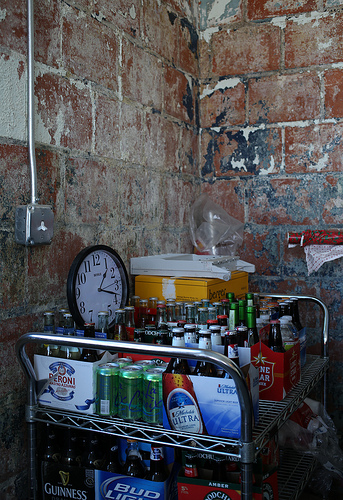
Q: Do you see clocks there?
A: Yes, there is a clock.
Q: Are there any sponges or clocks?
A: Yes, there is a clock.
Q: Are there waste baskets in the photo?
A: No, there are no waste baskets.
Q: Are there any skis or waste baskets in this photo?
A: No, there are no waste baskets or skis.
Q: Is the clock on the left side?
A: Yes, the clock is on the left of the image.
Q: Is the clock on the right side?
A: No, the clock is on the left of the image.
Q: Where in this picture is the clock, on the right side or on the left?
A: The clock is on the left of the image.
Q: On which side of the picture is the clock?
A: The clock is on the left of the image.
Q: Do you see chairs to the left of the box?
A: No, there is a clock to the left of the box.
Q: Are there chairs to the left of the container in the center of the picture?
A: No, there is a clock to the left of the box.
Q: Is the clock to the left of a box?
A: Yes, the clock is to the left of a box.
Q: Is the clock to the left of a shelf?
A: No, the clock is to the left of a box.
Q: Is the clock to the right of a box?
A: No, the clock is to the left of a box.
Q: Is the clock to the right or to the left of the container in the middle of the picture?
A: The clock is to the left of the box.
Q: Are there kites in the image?
A: No, there are no kites.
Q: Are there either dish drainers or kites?
A: No, there are no kites or dish drainers.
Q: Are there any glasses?
A: No, there are no glasses.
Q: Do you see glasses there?
A: No, there are no glasses.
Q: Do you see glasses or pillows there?
A: No, there are no glasses or pillows.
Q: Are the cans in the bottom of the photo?
A: Yes, the cans are in the bottom of the image.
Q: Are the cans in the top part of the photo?
A: No, the cans are in the bottom of the image.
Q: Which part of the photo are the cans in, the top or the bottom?
A: The cans are in the bottom of the image.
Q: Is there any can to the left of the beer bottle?
A: Yes, there are cans to the left of the beer bottle.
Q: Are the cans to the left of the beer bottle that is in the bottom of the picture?
A: Yes, the cans are to the left of the beer bottle.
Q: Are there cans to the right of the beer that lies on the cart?
A: Yes, there are cans to the right of the beer.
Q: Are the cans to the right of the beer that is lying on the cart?
A: Yes, the cans are to the right of the beer.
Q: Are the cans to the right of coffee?
A: No, the cans are to the right of the beer.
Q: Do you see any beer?
A: Yes, there is beer.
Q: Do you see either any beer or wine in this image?
A: Yes, there is beer.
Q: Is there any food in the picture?
A: No, there is no food.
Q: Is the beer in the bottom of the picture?
A: Yes, the beer is in the bottom of the image.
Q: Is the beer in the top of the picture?
A: No, the beer is in the bottom of the image.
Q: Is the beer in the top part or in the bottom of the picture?
A: The beer is in the bottom of the image.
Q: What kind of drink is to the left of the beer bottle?
A: The drink is beer.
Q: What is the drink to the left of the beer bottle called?
A: The drink is beer.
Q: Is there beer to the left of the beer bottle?
A: Yes, there is beer to the left of the beer bottle.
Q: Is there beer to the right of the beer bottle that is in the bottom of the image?
A: No, the beer is to the left of the beer bottle.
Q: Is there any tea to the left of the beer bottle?
A: No, there is beer to the left of the beer bottle.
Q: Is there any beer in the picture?
A: Yes, there is beer.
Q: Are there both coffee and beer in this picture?
A: No, there is beer but no coffee.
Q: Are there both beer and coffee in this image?
A: No, there is beer but no coffee.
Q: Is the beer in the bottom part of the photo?
A: Yes, the beer is in the bottom of the image.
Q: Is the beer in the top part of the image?
A: No, the beer is in the bottom of the image.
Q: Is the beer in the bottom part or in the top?
A: The beer is in the bottom of the image.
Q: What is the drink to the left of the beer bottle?
A: The drink is beer.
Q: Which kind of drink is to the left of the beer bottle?
A: The drink is beer.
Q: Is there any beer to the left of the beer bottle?
A: Yes, there is beer to the left of the beer bottle.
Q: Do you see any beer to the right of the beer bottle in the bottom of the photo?
A: No, the beer is to the left of the beer bottle.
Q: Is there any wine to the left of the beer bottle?
A: No, there is beer to the left of the beer bottle.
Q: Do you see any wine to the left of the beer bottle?
A: No, there is beer to the left of the beer bottle.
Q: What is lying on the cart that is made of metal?
A: The beer is lying on the cart.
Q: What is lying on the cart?
A: The beer is lying on the cart.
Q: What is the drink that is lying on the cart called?
A: The drink is beer.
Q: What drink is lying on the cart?
A: The drink is beer.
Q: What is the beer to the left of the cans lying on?
A: The beer is lying on the cart.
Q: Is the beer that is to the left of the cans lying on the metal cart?
A: Yes, the beer is lying on the cart.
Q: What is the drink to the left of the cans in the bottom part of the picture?
A: The drink is beer.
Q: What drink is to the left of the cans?
A: The drink is beer.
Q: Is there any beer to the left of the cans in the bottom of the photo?
A: Yes, there is beer to the left of the cans.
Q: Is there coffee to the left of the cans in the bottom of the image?
A: No, there is beer to the left of the cans.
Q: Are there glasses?
A: No, there are no glasses.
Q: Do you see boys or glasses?
A: No, there are no glasses or boys.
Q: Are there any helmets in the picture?
A: No, there are no helmets.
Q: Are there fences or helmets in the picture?
A: No, there are no helmets or fences.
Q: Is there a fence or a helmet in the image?
A: No, there are no helmets or fences.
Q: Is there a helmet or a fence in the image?
A: No, there are no helmets or fences.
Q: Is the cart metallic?
A: Yes, the cart is metallic.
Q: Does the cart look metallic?
A: Yes, the cart is metallic.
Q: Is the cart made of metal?
A: Yes, the cart is made of metal.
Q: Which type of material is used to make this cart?
A: The cart is made of metal.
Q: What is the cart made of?
A: The cart is made of metal.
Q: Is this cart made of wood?
A: No, the cart is made of metal.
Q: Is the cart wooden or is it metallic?
A: The cart is metallic.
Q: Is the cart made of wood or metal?
A: The cart is made of metal.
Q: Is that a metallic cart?
A: Yes, that is a metallic cart.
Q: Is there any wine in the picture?
A: No, there is no wine.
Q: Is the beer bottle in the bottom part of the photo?
A: Yes, the beer bottle is in the bottom of the image.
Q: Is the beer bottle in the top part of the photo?
A: No, the beer bottle is in the bottom of the image.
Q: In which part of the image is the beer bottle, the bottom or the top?
A: The beer bottle is in the bottom of the image.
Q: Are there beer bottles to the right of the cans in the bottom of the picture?
A: Yes, there is a beer bottle to the right of the cans.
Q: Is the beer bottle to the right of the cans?
A: Yes, the beer bottle is to the right of the cans.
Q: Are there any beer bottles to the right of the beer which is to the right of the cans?
A: Yes, there is a beer bottle to the right of the beer.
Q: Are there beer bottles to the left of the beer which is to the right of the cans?
A: No, the beer bottle is to the right of the beer.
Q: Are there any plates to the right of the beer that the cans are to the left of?
A: No, there is a beer bottle to the right of the beer.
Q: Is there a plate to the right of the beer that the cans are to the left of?
A: No, there is a beer bottle to the right of the beer.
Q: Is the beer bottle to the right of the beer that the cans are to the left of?
A: Yes, the beer bottle is to the right of the beer.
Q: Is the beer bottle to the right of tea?
A: No, the beer bottle is to the right of the beer.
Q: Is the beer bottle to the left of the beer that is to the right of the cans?
A: No, the beer bottle is to the right of the beer.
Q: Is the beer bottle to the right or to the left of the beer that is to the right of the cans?
A: The beer bottle is to the right of the beer.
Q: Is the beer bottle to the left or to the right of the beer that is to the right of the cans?
A: The beer bottle is to the right of the beer.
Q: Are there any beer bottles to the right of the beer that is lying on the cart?
A: Yes, there is a beer bottle to the right of the beer.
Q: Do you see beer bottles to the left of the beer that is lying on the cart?
A: No, the beer bottle is to the right of the beer.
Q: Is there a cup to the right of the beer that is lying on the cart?
A: No, there is a beer bottle to the right of the beer.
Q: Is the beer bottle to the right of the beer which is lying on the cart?
A: Yes, the beer bottle is to the right of the beer.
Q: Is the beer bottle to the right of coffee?
A: No, the beer bottle is to the right of the beer.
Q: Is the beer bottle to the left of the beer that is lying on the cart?
A: No, the beer bottle is to the right of the beer.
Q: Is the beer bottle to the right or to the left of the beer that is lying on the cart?
A: The beer bottle is to the right of the beer.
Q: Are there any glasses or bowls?
A: No, there are no glasses or bowls.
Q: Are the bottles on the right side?
A: Yes, the bottles are on the right of the image.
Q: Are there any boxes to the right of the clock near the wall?
A: Yes, there is a box to the right of the clock.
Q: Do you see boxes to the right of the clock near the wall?
A: Yes, there is a box to the right of the clock.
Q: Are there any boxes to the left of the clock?
A: No, the box is to the right of the clock.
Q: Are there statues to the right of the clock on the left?
A: No, there is a box to the right of the clock.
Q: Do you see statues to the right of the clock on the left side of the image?
A: No, there is a box to the right of the clock.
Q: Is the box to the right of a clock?
A: Yes, the box is to the right of a clock.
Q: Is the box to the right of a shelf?
A: No, the box is to the right of a clock.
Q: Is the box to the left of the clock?
A: No, the box is to the right of the clock.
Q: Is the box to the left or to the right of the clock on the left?
A: The box is to the right of the clock.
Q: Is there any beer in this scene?
A: Yes, there is beer.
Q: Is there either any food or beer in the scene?
A: Yes, there is beer.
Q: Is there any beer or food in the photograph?
A: Yes, there is beer.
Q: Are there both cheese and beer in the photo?
A: No, there is beer but no cheese.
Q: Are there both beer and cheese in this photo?
A: No, there is beer but no cheese.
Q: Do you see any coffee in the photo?
A: No, there is no coffee.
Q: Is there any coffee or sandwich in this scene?
A: No, there are no coffee or sandwiches.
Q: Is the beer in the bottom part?
A: Yes, the beer is in the bottom of the image.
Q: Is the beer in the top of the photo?
A: No, the beer is in the bottom of the image.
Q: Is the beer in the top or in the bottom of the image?
A: The beer is in the bottom of the image.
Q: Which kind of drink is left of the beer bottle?
A: The drink is beer.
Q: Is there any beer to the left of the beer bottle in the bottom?
A: Yes, there is beer to the left of the beer bottle.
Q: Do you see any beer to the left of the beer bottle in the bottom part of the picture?
A: Yes, there is beer to the left of the beer bottle.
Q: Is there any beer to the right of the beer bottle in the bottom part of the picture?
A: No, the beer is to the left of the beer bottle.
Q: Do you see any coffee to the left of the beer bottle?
A: No, there is beer to the left of the beer bottle.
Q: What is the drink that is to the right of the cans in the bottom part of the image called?
A: The drink is beer.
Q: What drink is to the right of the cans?
A: The drink is beer.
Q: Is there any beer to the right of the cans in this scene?
A: Yes, there is beer to the right of the cans.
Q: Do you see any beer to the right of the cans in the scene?
A: Yes, there is beer to the right of the cans.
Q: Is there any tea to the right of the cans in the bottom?
A: No, there is beer to the right of the cans.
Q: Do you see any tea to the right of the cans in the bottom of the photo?
A: No, there is beer to the right of the cans.